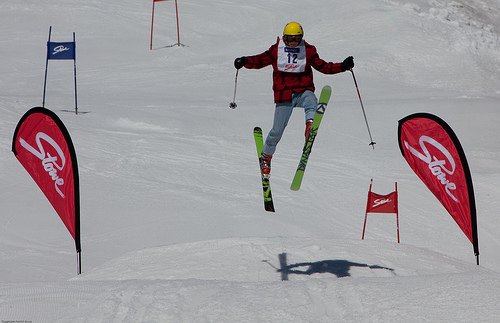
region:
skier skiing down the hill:
[225, 20, 377, 212]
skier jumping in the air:
[230, 21, 375, 213]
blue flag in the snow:
[36, 27, 79, 112]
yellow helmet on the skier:
[281, 22, 303, 43]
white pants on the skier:
[258, 90, 318, 162]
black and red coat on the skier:
[242, 43, 344, 103]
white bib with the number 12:
[277, 44, 306, 74]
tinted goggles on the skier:
[281, 33, 302, 45]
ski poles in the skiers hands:
[226, 55, 374, 147]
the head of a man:
[274, 13, 332, 61]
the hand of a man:
[218, 53, 260, 89]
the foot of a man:
[258, 148, 287, 178]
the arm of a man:
[239, 30, 299, 91]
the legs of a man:
[250, 80, 366, 190]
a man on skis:
[219, 28, 368, 218]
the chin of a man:
[272, 38, 308, 60]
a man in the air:
[211, 15, 404, 227]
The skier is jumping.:
[229, 21, 376, 212]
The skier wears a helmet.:
[283, 21, 300, 36]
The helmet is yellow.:
[281, 21, 304, 37]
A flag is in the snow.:
[10, 105, 82, 275]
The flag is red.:
[60, 202, 72, 218]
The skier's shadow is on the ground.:
[262, 251, 396, 282]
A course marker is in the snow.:
[359, 177, 403, 243]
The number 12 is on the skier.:
[283, 53, 299, 63]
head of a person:
[275, 19, 309, 56]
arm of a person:
[256, 34, 283, 72]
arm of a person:
[305, 41, 342, 76]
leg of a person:
[256, 107, 291, 150]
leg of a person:
[303, 82, 334, 117]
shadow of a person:
[314, 257, 353, 273]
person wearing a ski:
[231, 100, 288, 216]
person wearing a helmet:
[263, 2, 336, 59]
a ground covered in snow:
[132, 161, 247, 268]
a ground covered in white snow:
[111, 169, 283, 311]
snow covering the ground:
[105, 161, 214, 287]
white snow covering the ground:
[141, 218, 212, 312]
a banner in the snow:
[17, 55, 165, 277]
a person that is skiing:
[199, 13, 397, 223]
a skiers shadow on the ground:
[260, 220, 395, 275]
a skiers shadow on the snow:
[257, 227, 397, 303]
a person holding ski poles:
[197, 26, 384, 223]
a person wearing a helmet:
[237, 23, 326, 153]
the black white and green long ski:
[252, 124, 275, 212]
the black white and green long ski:
[290, 87, 332, 189]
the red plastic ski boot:
[259, 150, 271, 173]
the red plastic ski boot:
[303, 120, 315, 140]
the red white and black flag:
[9, 107, 83, 278]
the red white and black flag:
[399, 113, 481, 263]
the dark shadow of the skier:
[260, 250, 393, 289]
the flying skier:
[229, 20, 356, 178]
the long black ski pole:
[229, 66, 241, 108]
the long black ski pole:
[347, 66, 375, 148]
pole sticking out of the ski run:
[358, 176, 374, 237]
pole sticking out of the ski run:
[391, 177, 399, 242]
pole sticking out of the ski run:
[171, 1, 179, 47]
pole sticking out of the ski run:
[147, 0, 157, 48]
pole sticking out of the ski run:
[71, 30, 76, 115]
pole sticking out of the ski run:
[40, 22, 50, 107]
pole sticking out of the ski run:
[340, 58, 372, 148]